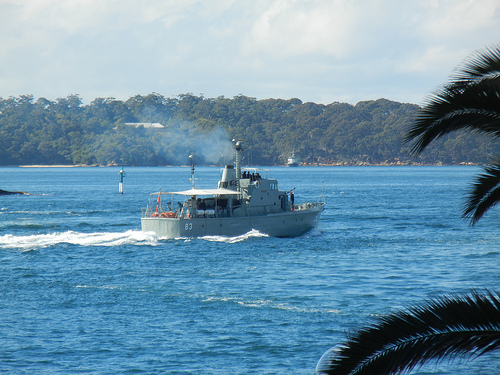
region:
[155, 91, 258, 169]
smoke coming from stack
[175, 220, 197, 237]
83 written in white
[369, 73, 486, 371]
palm tree leaves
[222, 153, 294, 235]
boat is grey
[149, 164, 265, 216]
canopy over the back of boat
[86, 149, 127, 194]
buoy in the water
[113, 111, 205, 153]
house surrounded by trees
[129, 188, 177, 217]
flag on the back of boat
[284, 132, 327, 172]
boat in the water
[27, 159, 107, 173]
shoreline along the water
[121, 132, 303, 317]
boat in the water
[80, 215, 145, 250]
white water behind boat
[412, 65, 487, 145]
tree next to the boat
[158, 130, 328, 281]
white boat in the water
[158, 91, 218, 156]
trees in the distance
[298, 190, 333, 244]
front part of boat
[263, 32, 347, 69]
clouds in the sky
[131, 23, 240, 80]
blue sky above clouds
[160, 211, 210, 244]
number on the boat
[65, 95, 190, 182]
many trees in the distance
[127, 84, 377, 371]
a boat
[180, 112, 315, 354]
a boat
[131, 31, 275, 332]
a boat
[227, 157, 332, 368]
a boat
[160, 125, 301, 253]
Steam coming out of boat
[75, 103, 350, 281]
Moving boat near land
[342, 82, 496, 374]
Green palm tree branches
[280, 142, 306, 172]
Small white boat in background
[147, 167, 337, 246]
Grey boat with number 83 printed on the side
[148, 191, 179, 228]
Orange life jackets on boat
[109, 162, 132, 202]
Black and white pole sticking out of water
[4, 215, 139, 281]
White wake produced by boat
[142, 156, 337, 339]
Boat moving in blue water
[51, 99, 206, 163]
White building surrounded by green trees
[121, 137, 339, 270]
a gray boat on the water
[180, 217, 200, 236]
numbers on the boat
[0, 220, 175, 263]
the white wake of the boat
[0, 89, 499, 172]
a row of green trees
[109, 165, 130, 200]
a buoy in the water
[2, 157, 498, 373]
a blue body of water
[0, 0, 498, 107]
a cloudy sky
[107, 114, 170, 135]
the roof of a building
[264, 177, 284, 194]
the bridge of the boat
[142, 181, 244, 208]
a white overhang